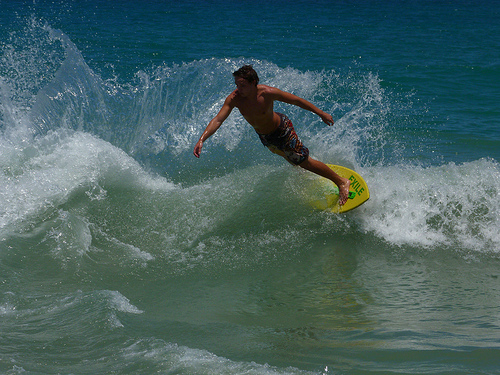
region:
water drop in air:
[91, 9, 97, 17]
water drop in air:
[108, 42, 116, 50]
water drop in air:
[123, 10, 130, 20]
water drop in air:
[12, 9, 19, 14]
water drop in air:
[14, 10, 20, 15]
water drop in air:
[14, 13, 23, 20]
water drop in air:
[27, 3, 31, 10]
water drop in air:
[470, 63, 477, 73]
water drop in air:
[357, 55, 369, 63]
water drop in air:
[149, 48, 156, 55]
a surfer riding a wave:
[116, 50, 401, 237]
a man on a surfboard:
[161, 65, 400, 240]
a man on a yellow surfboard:
[134, 38, 398, 235]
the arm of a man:
[266, 81, 347, 128]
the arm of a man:
[172, 90, 240, 180]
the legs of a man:
[284, 130, 354, 205]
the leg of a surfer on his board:
[288, 148, 354, 208]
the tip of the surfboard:
[292, 148, 378, 225]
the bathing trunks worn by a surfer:
[255, 112, 313, 172]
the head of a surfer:
[222, 59, 262, 101]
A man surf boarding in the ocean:
[192, 62, 352, 202]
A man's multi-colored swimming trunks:
[255, 114, 308, 166]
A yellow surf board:
[298, 160, 368, 210]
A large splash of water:
[2, 18, 392, 153]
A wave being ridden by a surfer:
[2, 127, 497, 254]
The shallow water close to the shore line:
[0, 234, 498, 373]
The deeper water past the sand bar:
[1, 0, 496, 135]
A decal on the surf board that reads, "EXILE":
[348, 173, 365, 195]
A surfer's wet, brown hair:
[232, 65, 259, 84]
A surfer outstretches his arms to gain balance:
[193, 82, 335, 156]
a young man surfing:
[161, 36, 418, 246]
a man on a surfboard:
[151, 41, 396, 232]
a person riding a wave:
[168, 46, 390, 228]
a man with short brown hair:
[173, 36, 353, 223]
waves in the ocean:
[14, 18, 481, 351]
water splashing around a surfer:
[12, 17, 381, 248]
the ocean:
[18, 1, 198, 353]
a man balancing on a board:
[153, 26, 411, 253]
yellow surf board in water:
[313, 170, 385, 211]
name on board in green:
[346, 174, 369, 202]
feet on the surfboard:
[324, 177, 353, 201]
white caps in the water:
[365, 157, 497, 243]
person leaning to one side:
[206, 93, 339, 190]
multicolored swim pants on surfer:
[271, 122, 310, 178]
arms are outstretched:
[160, 101, 337, 145]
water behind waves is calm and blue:
[98, 11, 486, 60]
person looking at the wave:
[77, 69, 272, 216]